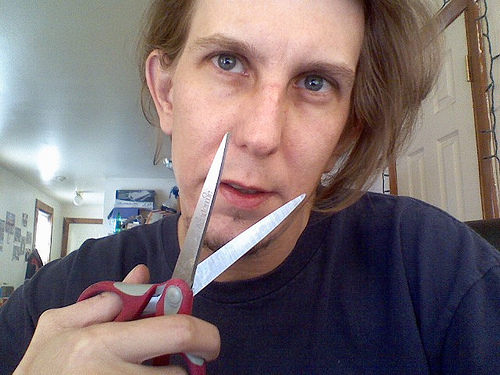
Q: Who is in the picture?
A: A woman.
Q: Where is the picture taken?
A: In a house.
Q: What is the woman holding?
A: Scissors.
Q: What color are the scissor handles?
A: Red.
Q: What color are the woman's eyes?
A: Blue.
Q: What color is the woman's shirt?
A: Blue.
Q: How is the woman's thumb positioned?
A: Through the scissors.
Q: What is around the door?
A: Christmas lights.